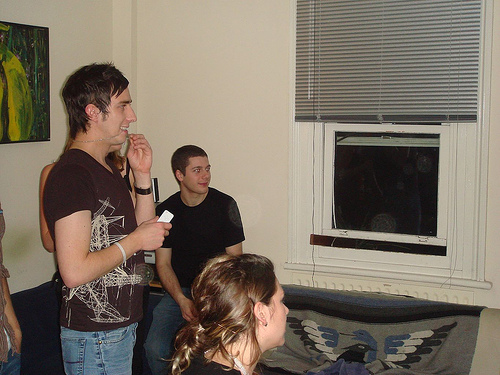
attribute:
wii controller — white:
[155, 209, 177, 222]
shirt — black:
[156, 188, 247, 287]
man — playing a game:
[142, 144, 247, 372]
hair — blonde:
[162, 253, 275, 375]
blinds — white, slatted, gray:
[293, 1, 481, 123]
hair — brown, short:
[171, 144, 209, 184]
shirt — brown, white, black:
[43, 149, 148, 333]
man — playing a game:
[40, 60, 174, 374]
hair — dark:
[60, 61, 131, 141]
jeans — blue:
[58, 322, 139, 372]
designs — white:
[59, 200, 143, 329]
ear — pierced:
[251, 301, 272, 329]